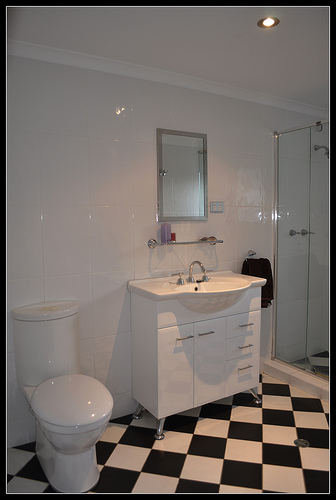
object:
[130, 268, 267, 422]
cabinet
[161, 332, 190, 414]
door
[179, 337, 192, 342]
handle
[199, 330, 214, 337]
handle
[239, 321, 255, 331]
drawer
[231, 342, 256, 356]
drawer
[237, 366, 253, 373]
drawer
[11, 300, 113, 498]
toliet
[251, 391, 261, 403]
leg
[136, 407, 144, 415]
leg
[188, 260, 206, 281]
faucet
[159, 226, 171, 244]
candle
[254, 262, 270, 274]
towel